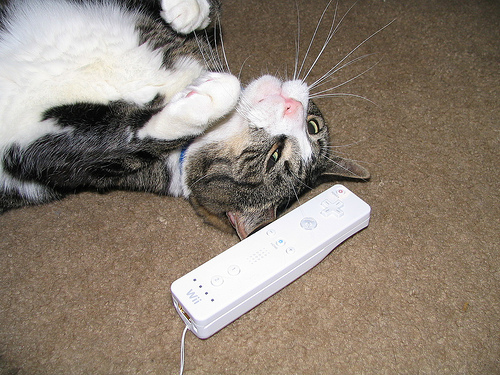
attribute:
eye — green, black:
[266, 136, 291, 172]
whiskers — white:
[192, 28, 397, 120]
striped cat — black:
[9, 7, 350, 202]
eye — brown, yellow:
[306, 117, 319, 132]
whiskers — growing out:
[310, 31, 381, 111]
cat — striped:
[11, 10, 369, 215]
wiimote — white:
[166, 180, 373, 373]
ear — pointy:
[313, 145, 379, 186]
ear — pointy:
[213, 194, 283, 243]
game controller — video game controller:
[165, 181, 372, 341]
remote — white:
[126, 174, 373, 340]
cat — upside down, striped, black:
[4, 1, 381, 243]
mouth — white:
[256, 71, 293, 106]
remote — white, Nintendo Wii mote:
[170, 183, 370, 338]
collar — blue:
[176, 142, 189, 195]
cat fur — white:
[0, 1, 205, 157]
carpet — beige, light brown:
[11, 6, 496, 372]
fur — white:
[0, 4, 187, 154]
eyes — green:
[251, 111, 325, 180]